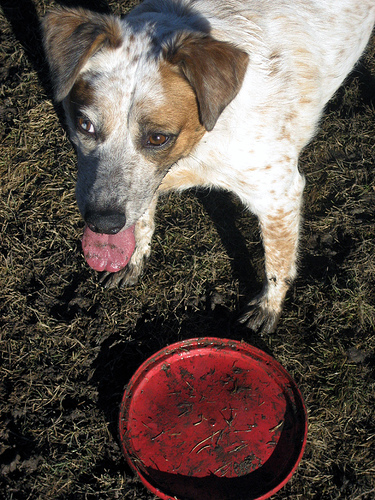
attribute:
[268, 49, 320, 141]
spots — brown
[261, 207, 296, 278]
spots — brown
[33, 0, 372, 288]
fur — white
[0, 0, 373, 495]
mud — brown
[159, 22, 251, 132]
ear — brown, floppy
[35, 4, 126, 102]
ear — brown, floppy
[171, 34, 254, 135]
ear — brown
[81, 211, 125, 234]
nose — black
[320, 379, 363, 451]
grass — green, muddy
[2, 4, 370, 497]
ground — red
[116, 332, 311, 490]
frisbee — dirty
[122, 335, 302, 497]
lid — red, muddy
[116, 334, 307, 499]
red plate — dirty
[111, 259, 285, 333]
paws — muddy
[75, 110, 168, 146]
eyes — brown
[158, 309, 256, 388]
plastic — part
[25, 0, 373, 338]
dog — muddy, brown, white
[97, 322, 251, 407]
mud — black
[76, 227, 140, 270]
tongue — pink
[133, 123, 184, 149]
eye — brown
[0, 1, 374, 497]
grass — green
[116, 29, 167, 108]
fur — white, dog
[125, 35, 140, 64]
spots — small, brown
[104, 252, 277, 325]
paws — muddy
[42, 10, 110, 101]
ear — brown